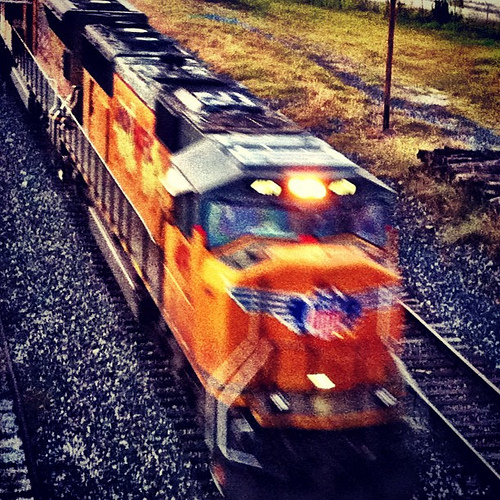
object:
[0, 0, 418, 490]
train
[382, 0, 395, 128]
log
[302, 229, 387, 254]
with wiper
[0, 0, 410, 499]
car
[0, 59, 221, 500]
gravel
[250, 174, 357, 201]
headlight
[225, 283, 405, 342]
logo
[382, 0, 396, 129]
pole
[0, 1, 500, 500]
tracks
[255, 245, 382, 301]
engine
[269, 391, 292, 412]
lights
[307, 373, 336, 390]
lights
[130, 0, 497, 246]
grass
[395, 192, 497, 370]
gravel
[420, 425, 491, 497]
gravel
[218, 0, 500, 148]
trail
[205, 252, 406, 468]
front engine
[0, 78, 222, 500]
rocks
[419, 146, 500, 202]
logs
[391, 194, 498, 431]
rocks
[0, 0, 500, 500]
ground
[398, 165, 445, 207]
dirt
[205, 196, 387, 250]
glass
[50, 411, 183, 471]
stone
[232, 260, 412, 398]
front portion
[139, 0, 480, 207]
area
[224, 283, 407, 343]
image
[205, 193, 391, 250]
window